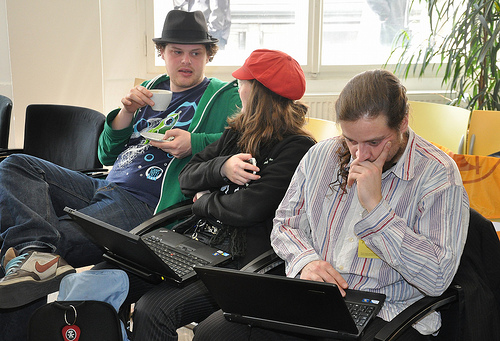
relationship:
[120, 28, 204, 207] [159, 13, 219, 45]
guy wearing hat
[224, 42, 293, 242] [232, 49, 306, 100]
girl wearing bill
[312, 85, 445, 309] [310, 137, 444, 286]
guy in shirt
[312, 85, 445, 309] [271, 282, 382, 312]
guy using keyboard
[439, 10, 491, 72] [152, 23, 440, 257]
tree behind them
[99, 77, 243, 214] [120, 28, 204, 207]
sweater of guy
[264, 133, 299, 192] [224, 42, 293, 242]
jacket of girl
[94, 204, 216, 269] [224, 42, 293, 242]
laptop of girl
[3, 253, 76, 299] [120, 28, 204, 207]
sneakers of guy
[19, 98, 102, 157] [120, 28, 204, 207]
chair next to guy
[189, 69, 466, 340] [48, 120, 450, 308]
guy on couch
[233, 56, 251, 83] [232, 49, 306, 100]
bill of bill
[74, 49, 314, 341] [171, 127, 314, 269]
girl wearing jacket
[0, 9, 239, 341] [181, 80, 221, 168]
guy wearing sweater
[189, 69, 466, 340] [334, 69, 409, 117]
guy with hair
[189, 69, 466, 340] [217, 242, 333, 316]
guy on laptop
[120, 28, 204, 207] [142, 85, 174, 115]
guy holding cup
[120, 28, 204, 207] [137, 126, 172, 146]
guy holding saucer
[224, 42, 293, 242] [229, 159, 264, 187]
girl holding phone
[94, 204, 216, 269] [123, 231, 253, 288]
laptop on lap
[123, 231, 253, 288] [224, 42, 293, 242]
lap of girl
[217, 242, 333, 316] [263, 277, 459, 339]
laptop on lap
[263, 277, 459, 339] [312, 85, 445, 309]
lap of guy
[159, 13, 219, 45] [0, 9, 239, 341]
hat of guy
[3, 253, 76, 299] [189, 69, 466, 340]
sneakers of guy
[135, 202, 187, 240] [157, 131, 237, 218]
arm of chair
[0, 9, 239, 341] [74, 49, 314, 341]
guy talking to girl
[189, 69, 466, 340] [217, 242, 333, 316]
guy looking at laptop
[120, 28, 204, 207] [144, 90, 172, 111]
guy holding cup